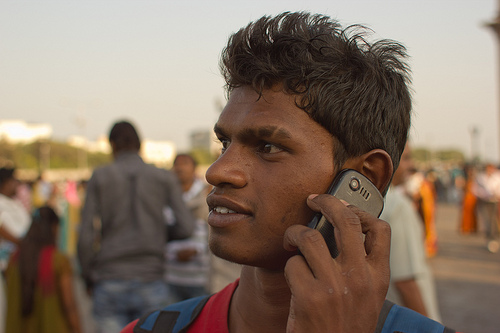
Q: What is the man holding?
A: Cell phone.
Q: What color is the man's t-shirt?
A: Red.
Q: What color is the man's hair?
A: Brown.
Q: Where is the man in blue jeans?
A: On the left.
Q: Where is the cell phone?
A: In the man's hand.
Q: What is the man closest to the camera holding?
A: Cell phone.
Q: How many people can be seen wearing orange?
A: Twp.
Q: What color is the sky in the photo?
A: Grey.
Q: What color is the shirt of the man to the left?
A: Grey.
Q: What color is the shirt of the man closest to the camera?
A: Red.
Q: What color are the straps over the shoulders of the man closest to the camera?
A: Blue.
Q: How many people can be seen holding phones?
A: One.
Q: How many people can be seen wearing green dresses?
A: One.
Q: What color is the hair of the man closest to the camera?
A: Black.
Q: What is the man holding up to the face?
A: Cell phone.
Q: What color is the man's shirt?
A: Red and blue.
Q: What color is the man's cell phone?
A: Grey.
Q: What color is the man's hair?
A: Dark brown.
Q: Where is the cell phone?
A: At the man's ear.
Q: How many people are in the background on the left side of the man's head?
A: Four.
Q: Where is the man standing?
A: Sidewalk.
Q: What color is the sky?
A: Blue.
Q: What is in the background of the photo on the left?
A: Trees.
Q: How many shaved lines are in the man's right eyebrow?
A: Two.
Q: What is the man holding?
A: Cell phone.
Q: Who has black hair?
A: The man.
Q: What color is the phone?
A: Black.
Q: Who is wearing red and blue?
A: Man on cell phone.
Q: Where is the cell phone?
A: In man's left hand.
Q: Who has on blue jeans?
A: Man in background.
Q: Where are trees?
A: In the distance.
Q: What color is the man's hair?
A: Black.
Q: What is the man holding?
A: Phone.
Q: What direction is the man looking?
A: To his right.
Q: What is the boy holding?
A: A phone.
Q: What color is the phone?
A: Black.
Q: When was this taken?
A: Summer.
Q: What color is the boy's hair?
A: Black.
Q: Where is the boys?
A: In the street.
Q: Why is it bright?
A: It's daylight.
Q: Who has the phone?
A: The boy.